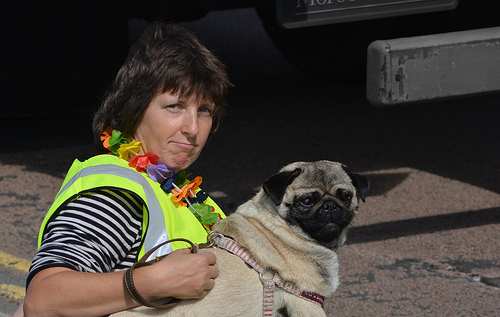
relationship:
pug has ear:
[108, 159, 370, 316] [262, 168, 302, 205]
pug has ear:
[108, 159, 370, 316] [342, 164, 369, 204]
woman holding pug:
[22, 21, 227, 316] [108, 159, 370, 316]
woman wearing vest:
[22, 21, 227, 316] [38, 155, 227, 262]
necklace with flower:
[102, 126, 222, 226] [129, 152, 160, 172]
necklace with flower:
[102, 126, 222, 226] [144, 164, 172, 183]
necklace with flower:
[102, 126, 222, 226] [170, 175, 202, 207]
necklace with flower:
[102, 126, 222, 226] [117, 141, 140, 162]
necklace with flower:
[102, 126, 222, 226] [107, 130, 127, 153]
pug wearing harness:
[108, 159, 370, 316] [208, 233, 325, 314]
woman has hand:
[22, 21, 227, 316] [160, 244, 218, 302]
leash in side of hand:
[124, 237, 198, 311] [160, 244, 218, 302]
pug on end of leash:
[108, 159, 370, 316] [124, 237, 198, 311]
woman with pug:
[22, 21, 227, 316] [108, 159, 370, 316]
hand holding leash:
[160, 244, 218, 302] [124, 237, 198, 311]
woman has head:
[22, 21, 227, 316] [95, 23, 232, 176]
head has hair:
[95, 23, 232, 176] [93, 24, 234, 139]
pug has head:
[108, 159, 370, 316] [269, 160, 367, 240]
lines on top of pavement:
[0, 249, 34, 303] [2, 118, 499, 317]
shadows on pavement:
[2, 97, 500, 246] [2, 118, 499, 317]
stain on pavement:
[374, 256, 420, 271] [2, 118, 499, 317]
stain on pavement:
[444, 257, 499, 274] [2, 118, 499, 317]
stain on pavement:
[2, 191, 40, 201] [2, 118, 499, 317]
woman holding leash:
[22, 21, 227, 316] [124, 237, 198, 311]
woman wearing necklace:
[22, 21, 227, 316] [102, 126, 222, 226]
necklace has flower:
[102, 126, 222, 226] [144, 164, 172, 183]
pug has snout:
[108, 159, 370, 316] [312, 199, 344, 228]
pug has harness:
[108, 159, 370, 316] [208, 233, 325, 314]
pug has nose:
[108, 159, 370, 316] [321, 200, 337, 213]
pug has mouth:
[108, 159, 370, 316] [316, 218, 344, 235]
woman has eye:
[22, 21, 227, 316] [163, 102, 184, 113]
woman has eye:
[22, 21, 227, 316] [198, 105, 212, 114]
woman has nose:
[22, 21, 227, 316] [180, 109, 200, 138]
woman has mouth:
[22, 21, 227, 316] [168, 139, 200, 149]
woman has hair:
[22, 21, 227, 316] [93, 24, 234, 139]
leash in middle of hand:
[124, 237, 198, 311] [160, 244, 218, 302]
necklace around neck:
[102, 126, 222, 226] [108, 135, 182, 181]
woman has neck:
[22, 21, 227, 316] [108, 135, 182, 181]